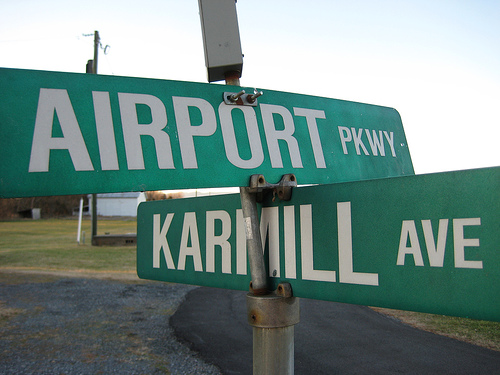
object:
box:
[195, 1, 248, 71]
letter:
[216, 100, 265, 170]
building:
[71, 187, 145, 218]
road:
[288, 302, 496, 371]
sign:
[0, 66, 413, 201]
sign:
[129, 180, 499, 327]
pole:
[244, 284, 301, 375]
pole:
[90, 31, 99, 244]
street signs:
[1, 139, 452, 372]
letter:
[117, 93, 176, 171]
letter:
[259, 101, 304, 169]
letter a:
[28, 87, 95, 171]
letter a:
[395, 219, 425, 267]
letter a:
[176, 212, 203, 273]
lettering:
[27, 86, 337, 181]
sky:
[4, 5, 500, 171]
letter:
[92, 91, 119, 171]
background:
[0, 0, 491, 131]